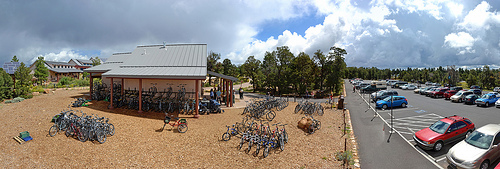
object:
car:
[443, 123, 499, 169]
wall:
[121, 79, 200, 103]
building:
[81, 41, 239, 118]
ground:
[0, 78, 499, 168]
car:
[373, 95, 409, 109]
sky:
[0, 0, 499, 71]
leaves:
[295, 71, 299, 74]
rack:
[220, 116, 290, 158]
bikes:
[273, 123, 288, 150]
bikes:
[220, 124, 240, 140]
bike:
[159, 112, 188, 133]